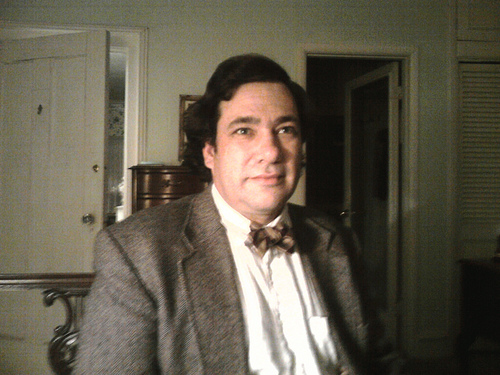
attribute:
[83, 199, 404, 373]
jacket — gray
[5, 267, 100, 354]
chair — intricate, bronze, brown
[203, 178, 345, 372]
shirt — white, white dress , collar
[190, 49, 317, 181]
hair — medium length brown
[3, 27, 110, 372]
white door — white 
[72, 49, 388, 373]
person — sitting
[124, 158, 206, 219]
amoire — jewelry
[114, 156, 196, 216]
drawers — small, chest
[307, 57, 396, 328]
room — dark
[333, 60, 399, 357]
door — full panel, glass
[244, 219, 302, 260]
tie — bow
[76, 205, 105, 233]
knob — door